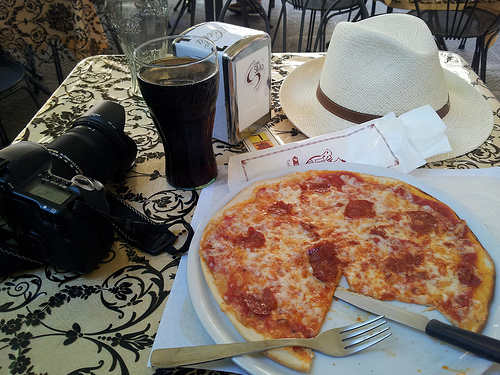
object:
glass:
[113, 0, 181, 104]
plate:
[192, 155, 497, 373]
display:
[27, 179, 71, 206]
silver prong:
[329, 313, 392, 358]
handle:
[425, 318, 499, 364]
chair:
[467, 2, 499, 81]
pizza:
[199, 168, 495, 368]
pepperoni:
[241, 284, 279, 316]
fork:
[149, 315, 398, 363]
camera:
[0, 96, 174, 279]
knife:
[334, 285, 496, 370]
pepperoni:
[343, 198, 376, 221]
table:
[0, 0, 499, 340]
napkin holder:
[170, 18, 277, 148]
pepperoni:
[306, 235, 342, 287]